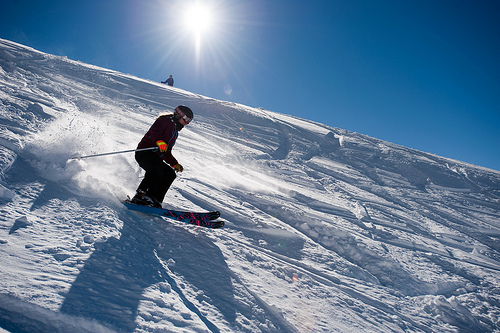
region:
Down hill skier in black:
[91, 100, 251, 236]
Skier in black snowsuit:
[90, 95, 251, 230]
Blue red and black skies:
[116, 190, 236, 250]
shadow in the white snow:
[51, 198, 284, 331]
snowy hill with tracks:
[0, 25, 435, 325]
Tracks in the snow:
[295, 175, 475, 300]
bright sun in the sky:
[135, 0, 276, 82]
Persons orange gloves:
[145, 132, 175, 162]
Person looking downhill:
[150, 58, 205, 98]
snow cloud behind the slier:
[20, 101, 240, 236]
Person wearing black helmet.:
[173, 107, 205, 146]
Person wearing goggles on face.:
[178, 108, 202, 140]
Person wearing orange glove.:
[156, 135, 183, 204]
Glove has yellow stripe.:
[149, 133, 202, 178]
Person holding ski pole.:
[70, 143, 199, 190]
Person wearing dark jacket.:
[131, 125, 203, 181]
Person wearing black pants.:
[114, 145, 191, 208]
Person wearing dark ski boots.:
[127, 180, 182, 235]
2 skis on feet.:
[143, 195, 241, 287]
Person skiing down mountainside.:
[54, 122, 239, 330]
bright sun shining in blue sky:
[140, 0, 234, 80]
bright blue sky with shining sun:
[34, 11, 494, 121]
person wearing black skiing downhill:
[70, 77, 235, 235]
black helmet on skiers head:
[157, 91, 201, 136]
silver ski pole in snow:
[60, 142, 165, 162]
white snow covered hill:
[221, 117, 495, 330]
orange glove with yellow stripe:
[153, 134, 173, 157]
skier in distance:
[161, 71, 181, 88]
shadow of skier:
[84, 185, 241, 327]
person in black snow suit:
[123, 94, 233, 244]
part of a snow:
[336, 239, 385, 296]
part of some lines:
[294, 257, 320, 287]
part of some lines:
[181, 206, 203, 224]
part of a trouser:
[137, 164, 152, 187]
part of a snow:
[261, 267, 312, 314]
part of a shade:
[228, 247, 266, 289]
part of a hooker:
[88, 142, 121, 179]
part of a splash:
[44, 125, 79, 170]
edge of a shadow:
[165, 281, 188, 310]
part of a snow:
[257, 242, 309, 283]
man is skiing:
[98, 105, 240, 230]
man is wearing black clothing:
[113, 94, 196, 219]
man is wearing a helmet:
[161, 102, 193, 124]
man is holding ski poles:
[49, 137, 166, 182]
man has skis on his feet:
[114, 192, 239, 236]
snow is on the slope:
[1, 35, 497, 332]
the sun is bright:
[131, 2, 248, 87]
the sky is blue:
[0, 0, 499, 183]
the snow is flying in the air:
[11, 98, 135, 207]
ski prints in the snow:
[128, 225, 243, 331]